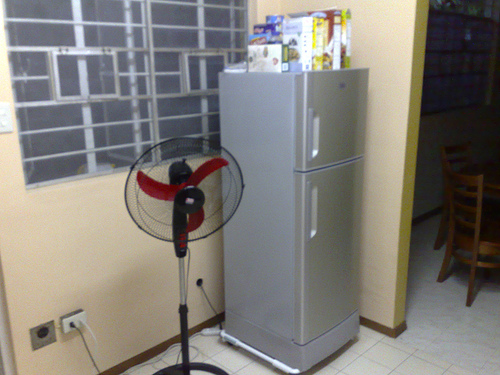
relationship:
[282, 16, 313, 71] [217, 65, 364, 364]
packet atop fridge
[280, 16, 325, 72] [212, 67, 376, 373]
cereal on top of fridge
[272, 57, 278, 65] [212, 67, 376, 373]
cereal on top of fridge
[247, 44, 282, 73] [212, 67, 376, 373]
boxes on top of fridge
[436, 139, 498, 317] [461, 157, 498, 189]
chairs under table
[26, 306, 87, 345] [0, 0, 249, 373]
outlets on wall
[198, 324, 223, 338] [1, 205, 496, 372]
surge protector on floor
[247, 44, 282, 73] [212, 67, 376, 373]
boxes on fridge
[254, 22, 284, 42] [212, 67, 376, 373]
boxes on fridge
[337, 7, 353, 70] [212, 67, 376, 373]
boxes on fridge